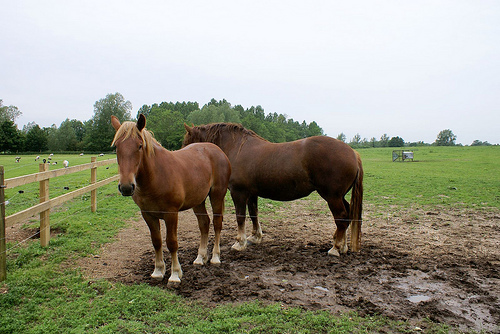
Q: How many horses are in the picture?
A: 2.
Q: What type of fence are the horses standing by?
A: Wooden.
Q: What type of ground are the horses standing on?
A: Muddy.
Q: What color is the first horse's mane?
A: Blonde.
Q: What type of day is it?
A: Cloudy.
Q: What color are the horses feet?
A: White.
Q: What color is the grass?
A: Green.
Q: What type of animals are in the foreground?
A: Horses.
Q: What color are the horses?
A: Brown.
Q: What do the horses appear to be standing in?
A: Mud.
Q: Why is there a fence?
A: To keep animals secure.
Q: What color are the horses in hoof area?
A: White.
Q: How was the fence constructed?
A: From wood.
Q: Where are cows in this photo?
A: In background.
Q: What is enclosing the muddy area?
A: Grass.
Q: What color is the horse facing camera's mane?
A: Blonde.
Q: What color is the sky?
A: Blue and white.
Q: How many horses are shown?
A: 2.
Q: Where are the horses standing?
A: In mud.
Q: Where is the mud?
A: Grass field.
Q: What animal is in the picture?
A: Horse.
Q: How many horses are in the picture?
A: Two.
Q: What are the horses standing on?
A: Mud.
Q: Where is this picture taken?
A: In a field.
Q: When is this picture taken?
A: Daytime.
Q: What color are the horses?
A: Brown.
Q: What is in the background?
A: Trees.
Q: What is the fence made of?
A: Wood.